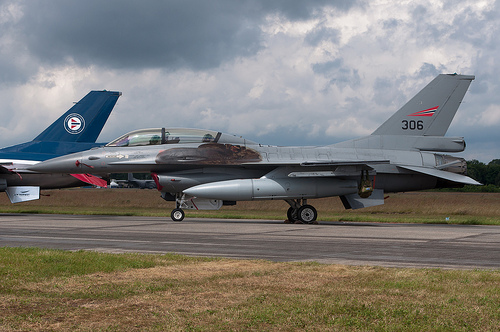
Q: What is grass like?
A: Dry.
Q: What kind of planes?
A: Fighters.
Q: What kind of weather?
A: Cloudy.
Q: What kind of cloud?
A: Dark.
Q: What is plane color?
A: Grey.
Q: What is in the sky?
A: Clouds.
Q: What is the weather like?
A: Cloudy.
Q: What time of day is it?
A: Afternoon.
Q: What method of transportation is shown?
A: Planes.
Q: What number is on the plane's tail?
A: 306.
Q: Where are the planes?
A: On the runway.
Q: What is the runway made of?
A: Cement.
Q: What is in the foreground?
A: Grass.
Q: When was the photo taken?
A: Daytime.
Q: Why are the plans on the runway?
A: They are going to take off.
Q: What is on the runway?
A: The planes.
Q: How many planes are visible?
A: Two.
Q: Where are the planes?
A: On the runway.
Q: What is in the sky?
A: Clouds.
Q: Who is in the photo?
A: Nobody.